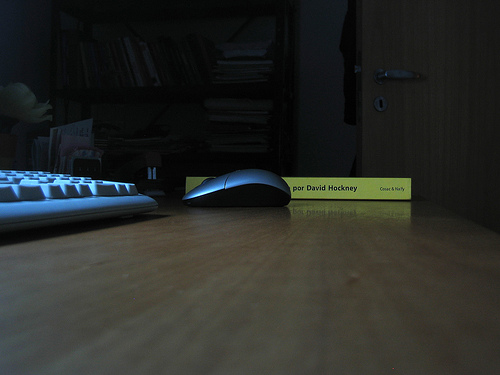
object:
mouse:
[178, 168, 290, 211]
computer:
[2, 155, 157, 231]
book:
[182, 176, 410, 198]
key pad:
[1, 164, 161, 233]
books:
[209, 98, 278, 107]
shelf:
[46, 8, 287, 171]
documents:
[123, 29, 163, 88]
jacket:
[338, 5, 362, 126]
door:
[357, 1, 499, 214]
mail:
[60, 134, 97, 169]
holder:
[72, 156, 102, 178]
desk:
[0, 160, 500, 374]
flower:
[1, 81, 52, 121]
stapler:
[108, 155, 167, 196]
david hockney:
[290, 182, 361, 195]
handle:
[372, 70, 425, 81]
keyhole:
[374, 99, 385, 111]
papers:
[56, 120, 102, 168]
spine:
[182, 174, 411, 201]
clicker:
[201, 176, 215, 185]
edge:
[78, 196, 146, 215]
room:
[1, 0, 499, 374]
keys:
[13, 178, 47, 201]